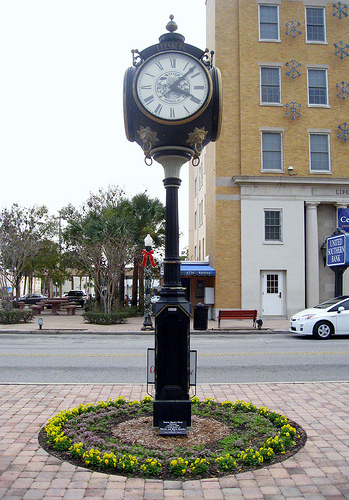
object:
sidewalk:
[1, 380, 347, 498]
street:
[1, 330, 348, 382]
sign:
[324, 233, 348, 267]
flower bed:
[41, 394, 301, 481]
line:
[2, 347, 349, 360]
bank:
[329, 253, 343, 264]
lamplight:
[139, 230, 157, 333]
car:
[287, 292, 348, 340]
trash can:
[191, 297, 210, 333]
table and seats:
[28, 295, 83, 319]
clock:
[119, 10, 227, 439]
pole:
[153, 151, 197, 439]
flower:
[168, 458, 179, 468]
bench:
[214, 304, 262, 332]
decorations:
[141, 249, 153, 321]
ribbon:
[141, 247, 157, 271]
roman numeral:
[166, 55, 181, 70]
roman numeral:
[153, 58, 167, 74]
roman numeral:
[141, 68, 159, 80]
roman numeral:
[134, 81, 157, 95]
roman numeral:
[142, 94, 156, 107]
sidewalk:
[0, 316, 292, 335]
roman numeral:
[154, 101, 167, 116]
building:
[184, 0, 348, 323]